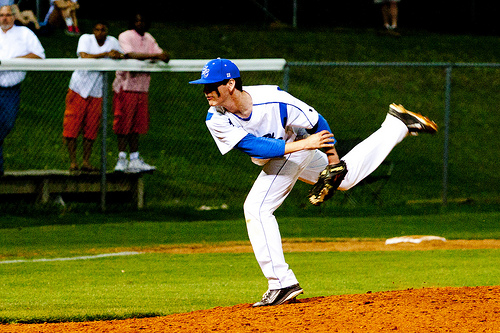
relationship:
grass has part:
[2, 251, 500, 323] [160, 258, 176, 279]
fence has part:
[2, 56, 499, 224] [370, 62, 440, 66]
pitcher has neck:
[183, 55, 443, 310] [221, 86, 255, 117]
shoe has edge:
[384, 96, 442, 140] [392, 98, 442, 127]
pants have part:
[240, 111, 415, 294] [359, 143, 380, 161]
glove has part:
[307, 160, 349, 211] [322, 161, 351, 177]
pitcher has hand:
[183, 55, 443, 310] [301, 129, 339, 155]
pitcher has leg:
[183, 55, 443, 310] [240, 157, 309, 310]